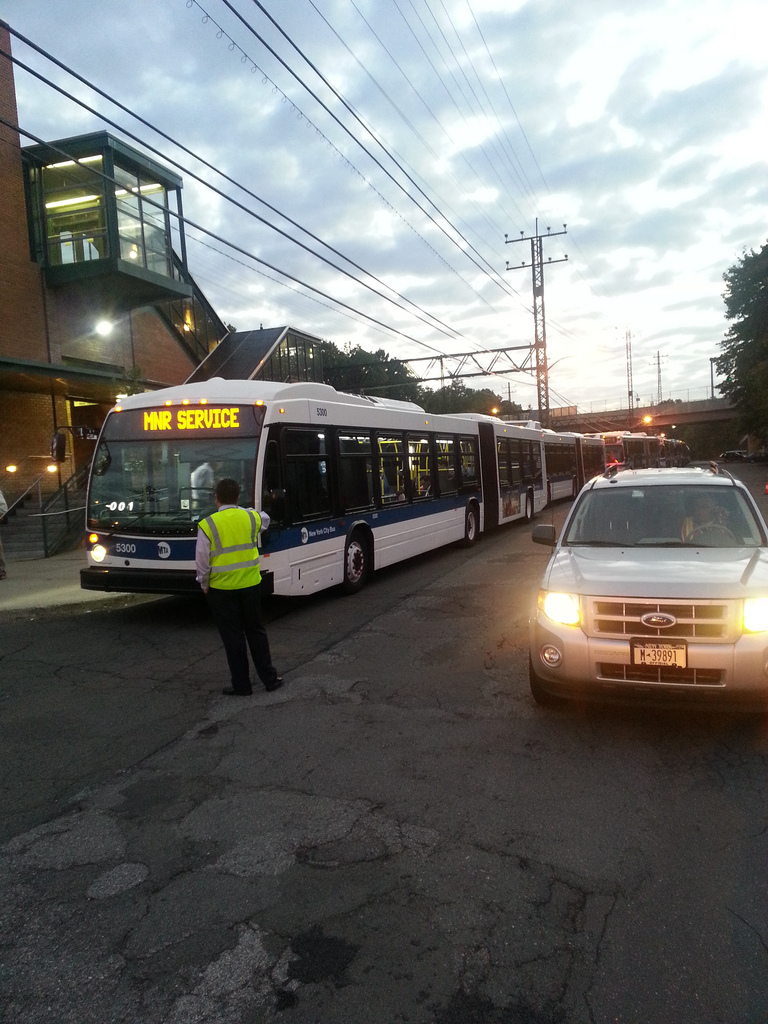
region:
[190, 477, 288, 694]
man standing in the sidewalk wearing yellow vest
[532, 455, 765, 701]
gray van with lights on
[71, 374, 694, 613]
large blue and white bus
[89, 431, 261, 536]
big windshield on blue and white bus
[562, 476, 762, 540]
windshield of gray car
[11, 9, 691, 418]
electrical wires connected to posts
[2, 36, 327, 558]
bricked building in the corner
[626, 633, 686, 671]
black and white license plate of gray car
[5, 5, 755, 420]
light blue cloudy sky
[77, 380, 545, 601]
a white double public service bus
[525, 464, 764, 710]
a silver SUV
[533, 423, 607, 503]
a white double public service bus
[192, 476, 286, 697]
a man standing in street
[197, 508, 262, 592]
a neon yellow safety vest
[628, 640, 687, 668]
a white license plate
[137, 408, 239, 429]
electronic bus destination sign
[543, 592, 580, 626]
a car front headlight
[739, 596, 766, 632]
a car front headlight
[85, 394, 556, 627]
the bus is white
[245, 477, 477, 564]
blue trim on the bus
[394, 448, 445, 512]
people on the bus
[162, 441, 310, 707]
person standing next to bus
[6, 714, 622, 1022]
patches on the ground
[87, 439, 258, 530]
glass is clean and clear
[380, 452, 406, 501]
glass is clean and clear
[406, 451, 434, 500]
glass is clean and clear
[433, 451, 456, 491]
glass is clean and clear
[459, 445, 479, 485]
glass is clean and clear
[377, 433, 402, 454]
glass is clean and clear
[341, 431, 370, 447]
glass is clean and clear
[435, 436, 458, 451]
glass is clean and clear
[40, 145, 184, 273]
a window on the building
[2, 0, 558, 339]
wires in the air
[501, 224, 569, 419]
a tall telephone pole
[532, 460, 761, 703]
a white car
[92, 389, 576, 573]
a large white and blue bus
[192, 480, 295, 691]
a man in a green vest